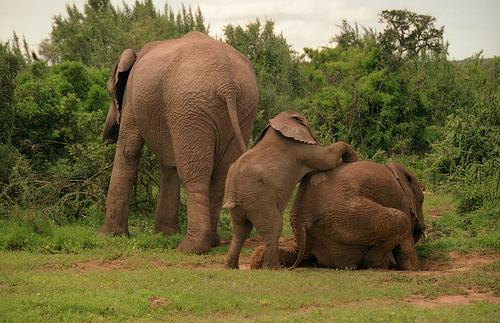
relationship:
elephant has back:
[288, 158, 428, 270] [295, 162, 394, 202]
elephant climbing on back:
[220, 109, 360, 269] [295, 162, 394, 202]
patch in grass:
[411, 288, 499, 307] [3, 222, 498, 321]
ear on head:
[271, 115, 316, 145] [270, 110, 319, 143]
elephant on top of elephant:
[220, 109, 360, 269] [288, 158, 428, 270]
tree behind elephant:
[39, 1, 214, 69] [100, 28, 263, 255]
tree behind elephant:
[377, 7, 450, 61] [288, 158, 428, 270]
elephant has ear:
[220, 109, 360, 269] [271, 115, 316, 145]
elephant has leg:
[220, 109, 360, 269] [248, 207, 284, 270]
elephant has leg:
[220, 109, 360, 269] [224, 208, 253, 268]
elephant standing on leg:
[220, 109, 360, 269] [248, 207, 284, 270]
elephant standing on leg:
[220, 109, 360, 269] [224, 208, 253, 268]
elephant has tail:
[100, 28, 263, 255] [223, 95, 246, 154]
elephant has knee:
[288, 158, 428, 270] [381, 205, 414, 242]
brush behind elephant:
[2, 61, 500, 186] [288, 158, 428, 270]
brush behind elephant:
[2, 61, 500, 186] [220, 109, 360, 269]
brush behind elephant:
[2, 61, 500, 186] [100, 28, 263, 255]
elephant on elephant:
[220, 109, 360, 269] [288, 158, 428, 270]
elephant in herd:
[288, 158, 428, 270] [100, 25, 430, 273]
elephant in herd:
[220, 109, 360, 269] [100, 25, 430, 273]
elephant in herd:
[100, 28, 263, 255] [100, 25, 430, 273]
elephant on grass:
[100, 28, 263, 255] [3, 222, 498, 321]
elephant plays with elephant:
[288, 158, 428, 270] [220, 109, 360, 269]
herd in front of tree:
[100, 25, 430, 273] [39, 1, 214, 69]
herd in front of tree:
[100, 25, 430, 273] [377, 7, 450, 61]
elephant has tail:
[220, 109, 360, 269] [223, 161, 238, 211]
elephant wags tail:
[220, 109, 360, 269] [223, 161, 238, 211]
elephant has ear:
[100, 28, 263, 255] [102, 48, 136, 144]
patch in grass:
[72, 258, 124, 271] [3, 222, 498, 321]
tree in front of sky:
[39, 1, 214, 69] [2, 0, 500, 62]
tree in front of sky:
[377, 7, 450, 61] [2, 0, 500, 62]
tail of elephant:
[287, 224, 311, 271] [288, 158, 428, 270]